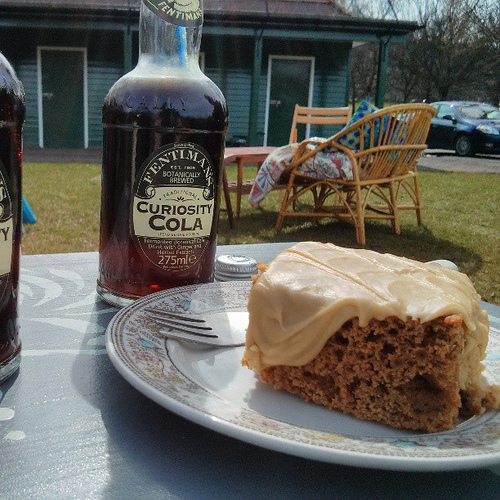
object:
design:
[107, 280, 500, 461]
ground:
[378, 162, 459, 210]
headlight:
[476, 123, 499, 135]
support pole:
[377, 42, 388, 109]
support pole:
[245, 34, 267, 146]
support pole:
[119, 27, 134, 77]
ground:
[422, 151, 446, 186]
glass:
[96, 0, 230, 308]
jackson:
[132, 141, 216, 273]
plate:
[106, 278, 500, 474]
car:
[386, 100, 499, 154]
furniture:
[223, 102, 435, 247]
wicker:
[257, 104, 436, 247]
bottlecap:
[213, 254, 259, 282]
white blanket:
[228, 108, 405, 181]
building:
[0, 0, 422, 165]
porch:
[19, 146, 104, 166]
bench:
[275, 102, 436, 249]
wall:
[243, 82, 293, 162]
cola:
[149, 214, 203, 231]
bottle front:
[95, 0, 229, 310]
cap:
[214, 254, 259, 281]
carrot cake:
[240, 240, 498, 436]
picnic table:
[221, 146, 306, 229]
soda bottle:
[98, 0, 233, 308]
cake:
[241, 240, 500, 431]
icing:
[243, 238, 499, 434]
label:
[129, 141, 219, 278]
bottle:
[96, 0, 228, 307]